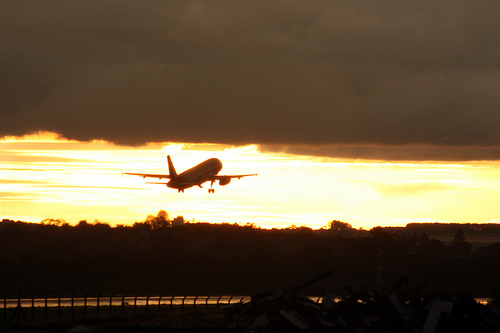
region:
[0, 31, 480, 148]
Dark clouds in the sky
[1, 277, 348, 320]
Long fence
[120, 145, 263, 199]
Aeroplane up in the air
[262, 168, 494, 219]
Bright light in the horizon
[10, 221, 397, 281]
Mass of thick shrubbery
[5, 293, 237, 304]
Runway behing the fence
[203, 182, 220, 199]
Landing gear of the aircraft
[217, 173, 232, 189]
One engine of the aircraft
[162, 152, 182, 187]
Tail end of the aircraft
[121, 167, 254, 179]
Wingspan of the aircraft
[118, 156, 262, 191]
Plane in sunlit sky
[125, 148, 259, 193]
Airplane in sunlit sky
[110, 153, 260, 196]
Airplane over dark trees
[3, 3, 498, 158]
Clouds over airplane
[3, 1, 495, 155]
Clouds over plane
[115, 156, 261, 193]
Airplane looks dark brown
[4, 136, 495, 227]
Clouds in sunlit sky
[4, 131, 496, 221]
Plane is golden yellow sky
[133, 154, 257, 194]
plane flying over trees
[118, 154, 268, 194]
Plane flying under dark clouds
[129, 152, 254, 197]
Airplane taking off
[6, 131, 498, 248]
Sun rising is bright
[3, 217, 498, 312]
Trees appear very dark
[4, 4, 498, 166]
Clouds appear very dark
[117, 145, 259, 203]
Airplane looks very dark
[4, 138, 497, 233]
Sky looks golden yellow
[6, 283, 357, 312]
Fence along the tree line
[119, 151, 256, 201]
Airplane flying in the sky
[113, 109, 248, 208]
air plane taking off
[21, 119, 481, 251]
bright sunny horizon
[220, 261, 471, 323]
pile of rubble near a landing strip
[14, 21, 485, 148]
large mass of grey clouds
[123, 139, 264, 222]
very large plane flying in the air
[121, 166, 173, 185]
long plane wing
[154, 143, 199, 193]
tall tail of a plane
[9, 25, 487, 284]
cloudy sky with orange sunlight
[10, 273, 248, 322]
fence along the edge of a landing strip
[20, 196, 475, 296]
line of trees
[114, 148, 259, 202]
a black plane in the sky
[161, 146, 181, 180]
a vertical stabilizer on a plane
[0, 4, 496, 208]
plane is traveling on a overcast sky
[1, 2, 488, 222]
sky is white and blue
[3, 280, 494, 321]
a train is passing below the plane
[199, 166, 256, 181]
right wing of a plane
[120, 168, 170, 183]
left wing of a plane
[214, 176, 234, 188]
engine of plane under right wing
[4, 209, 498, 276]
trees are growing below tree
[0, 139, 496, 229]
sky is yellow and white